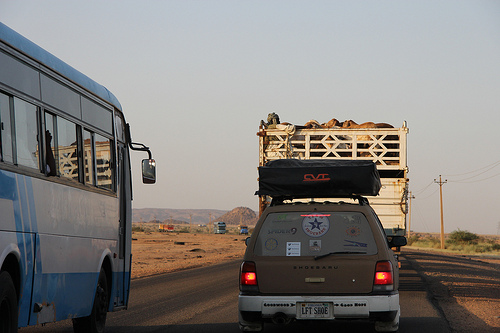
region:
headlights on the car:
[376, 260, 391, 288]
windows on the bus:
[3, 118, 111, 183]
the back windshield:
[270, 216, 372, 254]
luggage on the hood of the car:
[259, 159, 377, 194]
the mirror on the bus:
[140, 155, 157, 182]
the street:
[167, 273, 227, 323]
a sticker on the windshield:
[300, 213, 331, 236]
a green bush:
[444, 225, 475, 244]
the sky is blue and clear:
[140, 29, 284, 107]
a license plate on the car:
[297, 301, 332, 317]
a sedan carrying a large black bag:
[241, 157, 399, 331]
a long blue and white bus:
[0, 21, 156, 326]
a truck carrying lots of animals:
[260, 112, 408, 233]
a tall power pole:
[434, 175, 446, 251]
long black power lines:
[439, 165, 499, 185]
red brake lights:
[373, 260, 393, 295]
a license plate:
[297, 300, 332, 318]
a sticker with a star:
[301, 214, 331, 236]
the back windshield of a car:
[257, 210, 377, 258]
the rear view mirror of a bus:
[140, 160, 157, 185]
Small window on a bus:
[89, 125, 139, 208]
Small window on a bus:
[75, 121, 103, 196]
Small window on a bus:
[52, 102, 93, 184]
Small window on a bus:
[9, 87, 54, 177]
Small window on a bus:
[0, 86, 17, 171]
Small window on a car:
[238, 190, 392, 262]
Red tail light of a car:
[366, 256, 401, 323]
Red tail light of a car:
[235, 256, 270, 294]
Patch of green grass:
[450, 225, 480, 252]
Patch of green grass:
[415, 222, 458, 252]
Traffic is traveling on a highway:
[5, 10, 497, 315]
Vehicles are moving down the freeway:
[10, 25, 481, 330]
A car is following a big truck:
[246, 12, 418, 322]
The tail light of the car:
[371, 257, 391, 292]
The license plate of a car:
[296, 300, 329, 317]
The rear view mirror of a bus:
[140, 157, 155, 182]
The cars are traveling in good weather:
[3, 6, 493, 326]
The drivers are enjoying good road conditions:
[6, 20, 496, 323]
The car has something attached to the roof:
[254, 158, 380, 326]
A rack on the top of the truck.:
[254, 154, 376, 202]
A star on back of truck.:
[306, 218, 326, 240]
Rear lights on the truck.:
[238, 262, 390, 298]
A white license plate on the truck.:
[291, 300, 350, 321]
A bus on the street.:
[21, 36, 152, 313]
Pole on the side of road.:
[430, 168, 459, 255]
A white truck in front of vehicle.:
[271, 123, 407, 220]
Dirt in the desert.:
[155, 225, 218, 261]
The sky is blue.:
[149, 9, 437, 125]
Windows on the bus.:
[18, 99, 130, 173]